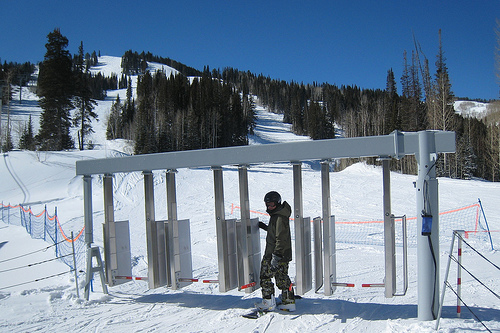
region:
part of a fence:
[454, 212, 456, 222]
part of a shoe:
[251, 307, 267, 324]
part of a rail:
[373, 267, 378, 269]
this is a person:
[256, 173, 325, 303]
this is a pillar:
[403, 150, 445, 308]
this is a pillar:
[374, 157, 420, 301]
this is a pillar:
[312, 163, 352, 290]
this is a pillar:
[271, 130, 321, 294]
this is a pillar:
[232, 159, 264, 290]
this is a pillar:
[203, 163, 247, 308]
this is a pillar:
[159, 180, 209, 297]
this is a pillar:
[119, 155, 166, 300]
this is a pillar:
[78, 169, 101, 274]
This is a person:
[236, 182, 322, 332]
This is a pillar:
[328, 210, 343, 299]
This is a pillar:
[309, 211, 332, 295]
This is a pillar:
[174, 211, 208, 297]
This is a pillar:
[155, 207, 172, 294]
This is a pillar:
[101, 170, 123, 299]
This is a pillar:
[80, 176, 100, 286]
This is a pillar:
[143, 168, 166, 295]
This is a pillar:
[209, 164, 235, 298]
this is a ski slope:
[27, 22, 450, 293]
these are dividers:
[59, 134, 404, 287]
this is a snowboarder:
[212, 166, 312, 303]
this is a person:
[227, 163, 293, 311]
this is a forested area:
[18, 16, 387, 134]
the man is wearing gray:
[262, 195, 314, 327]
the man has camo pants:
[249, 258, 327, 315]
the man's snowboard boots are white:
[232, 291, 310, 330]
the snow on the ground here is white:
[62, 281, 176, 326]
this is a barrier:
[50, 216, 108, 281]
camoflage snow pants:
[261, 249, 293, 299]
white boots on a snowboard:
[237, 298, 296, 323]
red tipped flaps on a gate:
[333, 277, 385, 291]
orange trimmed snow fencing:
[79, 127, 461, 321]